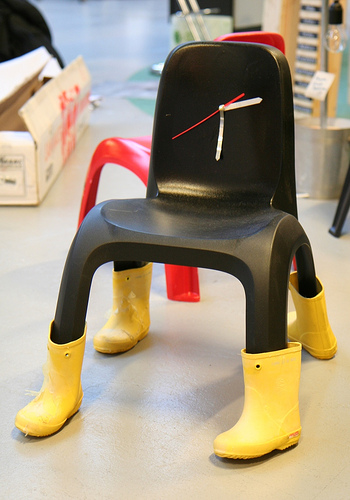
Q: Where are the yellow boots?
A: Legs of the black chair.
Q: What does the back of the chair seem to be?
A: Face of analog clock.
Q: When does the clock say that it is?
A: 2:30.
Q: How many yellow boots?
A: Four.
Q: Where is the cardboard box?
A: Upper left of photo.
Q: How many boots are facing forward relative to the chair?
A: Three.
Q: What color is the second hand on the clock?
A: Red.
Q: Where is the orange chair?
A: Behind black chair.